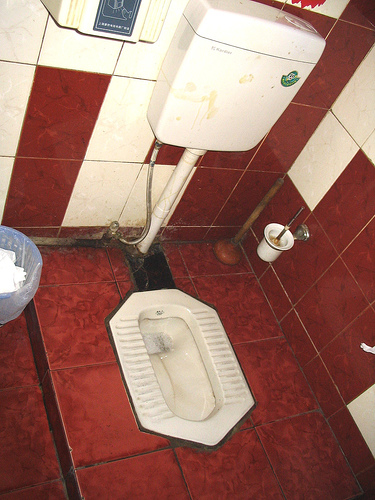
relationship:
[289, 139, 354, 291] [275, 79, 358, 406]
tile on walls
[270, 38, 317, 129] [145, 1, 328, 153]
sticker on toilet tank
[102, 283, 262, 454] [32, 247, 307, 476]
toilet in floor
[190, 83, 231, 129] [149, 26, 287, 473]
stains on toilet bowl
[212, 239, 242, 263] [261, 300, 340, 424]
plunger on floor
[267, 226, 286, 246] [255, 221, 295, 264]
cleaner in cleaner container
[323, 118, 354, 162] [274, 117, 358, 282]
tile on wall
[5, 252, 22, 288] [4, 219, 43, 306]
tissues in trashcan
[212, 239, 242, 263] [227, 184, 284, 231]
plunger with wood handle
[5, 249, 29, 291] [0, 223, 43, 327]
garbage in waste basket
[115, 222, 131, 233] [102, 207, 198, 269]
dust bunnies on pipes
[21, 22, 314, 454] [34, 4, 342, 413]
photograph of bathroom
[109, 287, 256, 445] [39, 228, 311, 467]
toilet in ground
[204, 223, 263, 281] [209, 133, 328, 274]
plunger in bathroom corner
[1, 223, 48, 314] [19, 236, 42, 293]
waste basket with plastic liner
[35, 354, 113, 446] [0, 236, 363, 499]
tile on floor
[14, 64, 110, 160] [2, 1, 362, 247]
tile on wall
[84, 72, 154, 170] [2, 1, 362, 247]
tile on wall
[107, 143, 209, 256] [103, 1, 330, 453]
plumbing for toilet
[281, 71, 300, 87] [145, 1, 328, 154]
sticker on toilet tank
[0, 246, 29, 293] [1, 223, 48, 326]
paper in basket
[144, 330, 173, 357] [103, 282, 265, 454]
water in toilet bowl